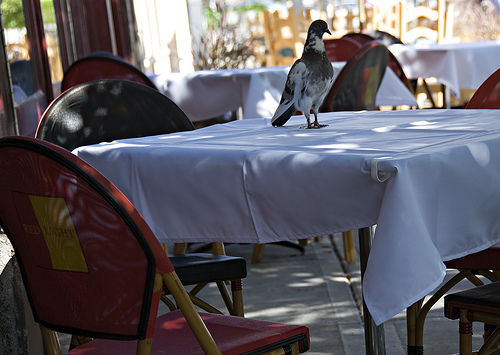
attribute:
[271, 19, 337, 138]
bird — gray, white, standing, dark gray, feathered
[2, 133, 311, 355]
chair — red, yellow, wood, foldable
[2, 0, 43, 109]
window — large, glass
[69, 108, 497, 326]
tablecloth — white, large, blue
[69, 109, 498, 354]
table — square, outdoors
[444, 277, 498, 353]
chair — brown, wood, wooden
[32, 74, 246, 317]
chair — black, red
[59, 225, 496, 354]
ground — gray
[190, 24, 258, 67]
bush — brown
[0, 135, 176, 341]
back — red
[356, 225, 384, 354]
leg — support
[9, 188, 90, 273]
design — yellow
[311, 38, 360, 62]
chair — red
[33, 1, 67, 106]
door — glass